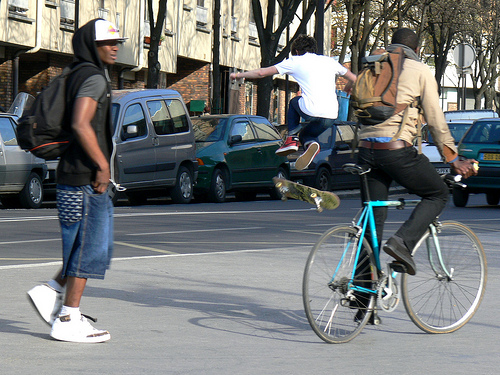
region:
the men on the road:
[17, 15, 486, 344]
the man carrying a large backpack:
[13, 18, 129, 344]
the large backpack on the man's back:
[17, 63, 75, 158]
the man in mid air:
[229, 34, 357, 171]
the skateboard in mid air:
[270, 175, 339, 211]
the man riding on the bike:
[302, 28, 486, 344]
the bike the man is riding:
[302, 159, 487, 342]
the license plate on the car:
[482, 152, 498, 159]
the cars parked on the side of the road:
[0, 91, 498, 203]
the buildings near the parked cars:
[0, 0, 499, 136]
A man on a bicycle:
[352, 8, 499, 295]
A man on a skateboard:
[268, 28, 326, 231]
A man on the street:
[19, 40, 149, 330]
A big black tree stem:
[147, 26, 166, 85]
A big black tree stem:
[247, 49, 274, 121]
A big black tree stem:
[207, 40, 224, 110]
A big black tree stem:
[342, 26, 351, 64]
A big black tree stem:
[473, 85, 485, 113]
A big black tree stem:
[489, 89, 496, 107]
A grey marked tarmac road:
[129, 195, 277, 257]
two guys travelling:
[10, 18, 489, 363]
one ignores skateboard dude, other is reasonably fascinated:
[8, 7, 493, 353]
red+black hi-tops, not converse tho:
[267, 127, 322, 172]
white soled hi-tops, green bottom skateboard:
[260, 140, 345, 220]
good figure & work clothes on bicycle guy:
[287, 10, 497, 360]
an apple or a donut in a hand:
[466, 156, 486, 172]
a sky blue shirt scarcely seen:
[356, 127, 396, 147]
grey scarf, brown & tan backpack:
[341, 35, 422, 150]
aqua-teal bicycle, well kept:
[298, 188, 495, 349]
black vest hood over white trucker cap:
[49, 14, 139, 196]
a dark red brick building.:
[185, 70, 210, 94]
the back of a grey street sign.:
[451, 35, 476, 109]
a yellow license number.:
[481, 147, 499, 165]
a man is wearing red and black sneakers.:
[274, 130, 321, 172]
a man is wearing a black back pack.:
[13, 58, 103, 162]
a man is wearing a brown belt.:
[354, 135, 416, 153]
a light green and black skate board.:
[268, 172, 343, 214]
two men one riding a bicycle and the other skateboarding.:
[225, 12, 487, 358]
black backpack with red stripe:
[13, 59, 106, 161]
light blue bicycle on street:
[298, 155, 491, 347]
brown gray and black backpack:
[349, 40, 431, 126]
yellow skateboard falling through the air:
[269, 171, 343, 215]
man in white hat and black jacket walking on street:
[9, 15, 128, 346]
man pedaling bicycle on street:
[338, 20, 477, 317]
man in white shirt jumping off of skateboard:
[227, 32, 370, 172]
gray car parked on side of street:
[28, 85, 200, 207]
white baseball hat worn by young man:
[71, 18, 130, 47]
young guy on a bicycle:
[342, 34, 473, 333]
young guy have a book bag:
[356, 26, 453, 273]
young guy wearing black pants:
[354, 28, 467, 298]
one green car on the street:
[456, 114, 498, 211]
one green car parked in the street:
[191, 98, 278, 202]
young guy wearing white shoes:
[20, 11, 121, 346]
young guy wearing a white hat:
[23, 15, 138, 335]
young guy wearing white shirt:
[232, 35, 339, 177]